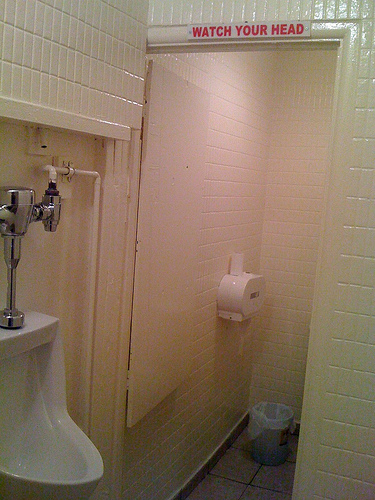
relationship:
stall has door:
[116, 46, 371, 490] [130, 64, 208, 426]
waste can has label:
[245, 404, 301, 473] [273, 429, 302, 450]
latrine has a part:
[116, 46, 371, 490] [221, 86, 321, 245]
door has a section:
[130, 64, 208, 426] [157, 65, 226, 165]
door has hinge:
[130, 64, 208, 426] [119, 361, 140, 399]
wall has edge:
[297, 72, 374, 493] [296, 52, 339, 422]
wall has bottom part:
[297, 72, 374, 493] [268, 454, 371, 497]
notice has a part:
[194, 22, 314, 56] [245, 5, 311, 52]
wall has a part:
[297, 72, 374, 493] [221, 86, 321, 245]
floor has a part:
[203, 449, 292, 498] [229, 431, 255, 456]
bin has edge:
[239, 391, 306, 459] [250, 400, 295, 428]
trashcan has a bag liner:
[245, 404, 301, 473] [245, 402, 298, 437]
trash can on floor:
[245, 404, 301, 473] [203, 449, 292, 498]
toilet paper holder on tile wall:
[212, 243, 267, 337] [203, 176, 259, 267]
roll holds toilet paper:
[225, 248, 253, 278] [212, 253, 272, 327]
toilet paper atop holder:
[227, 239, 268, 286] [213, 269, 289, 323]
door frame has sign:
[116, 46, 371, 490] [168, 19, 317, 47]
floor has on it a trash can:
[203, 449, 292, 498] [245, 404, 301, 473]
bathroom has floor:
[116, 46, 371, 490] [203, 449, 292, 498]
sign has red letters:
[168, 19, 317, 47] [183, 24, 306, 39]